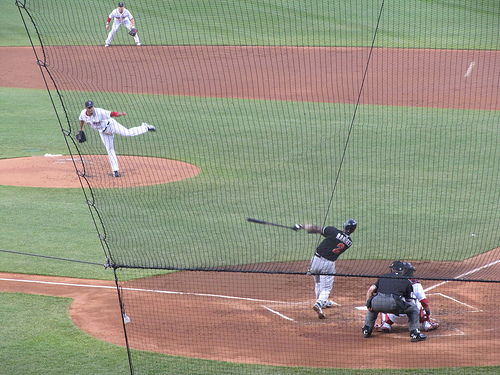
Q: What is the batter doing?
A: Swinging his bat.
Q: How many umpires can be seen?
A: One.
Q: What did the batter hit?
A: Baseball.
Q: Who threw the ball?
A: Pitcher.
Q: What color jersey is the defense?
A: White.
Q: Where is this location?
A: Baseball field.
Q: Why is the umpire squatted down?
A: To see pitches.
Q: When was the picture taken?
A: During a baseball game.